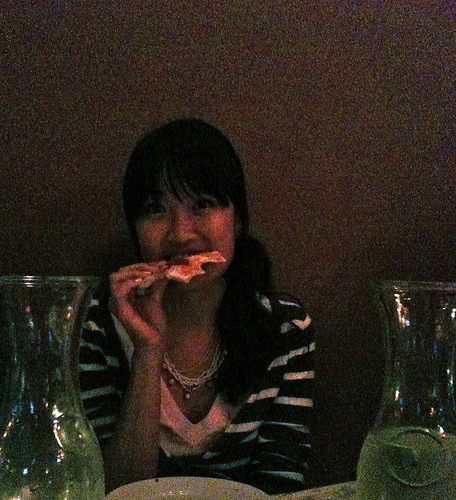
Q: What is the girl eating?
A: Pizza.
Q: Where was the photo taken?
A: Restaurant.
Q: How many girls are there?
A: One.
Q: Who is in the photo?
A: A girl.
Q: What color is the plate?
A: White.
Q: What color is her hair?
A: Black.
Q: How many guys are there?
A: None.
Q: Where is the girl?
A: At a table in a restaurant.